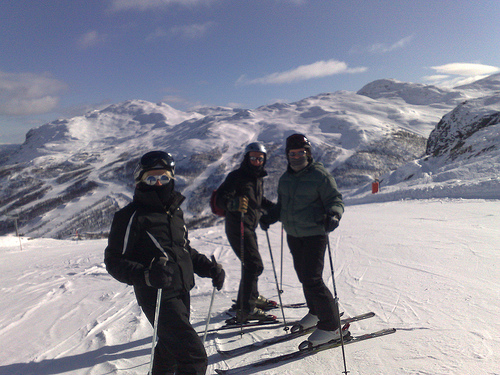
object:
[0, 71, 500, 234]
mountain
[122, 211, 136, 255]
stripe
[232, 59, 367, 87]
cloud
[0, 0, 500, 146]
cloud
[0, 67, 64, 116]
cloud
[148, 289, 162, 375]
ski pole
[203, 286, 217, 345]
ski pole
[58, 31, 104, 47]
cloud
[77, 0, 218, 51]
cloud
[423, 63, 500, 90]
cloud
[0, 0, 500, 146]
sky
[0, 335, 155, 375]
shadow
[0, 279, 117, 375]
snow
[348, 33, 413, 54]
cloud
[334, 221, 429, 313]
hill side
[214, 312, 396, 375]
gray skis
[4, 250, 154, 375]
tracks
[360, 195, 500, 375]
snow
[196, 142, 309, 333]
outfit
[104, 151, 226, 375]
outfit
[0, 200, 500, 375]
hillside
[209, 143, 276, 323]
person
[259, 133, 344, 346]
person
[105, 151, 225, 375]
person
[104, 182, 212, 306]
coat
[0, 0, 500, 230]
background